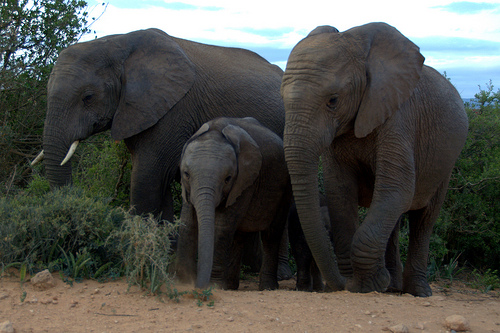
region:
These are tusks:
[24, 136, 137, 209]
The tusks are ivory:
[23, 125, 95, 177]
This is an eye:
[180, 171, 201, 182]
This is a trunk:
[200, 198, 213, 295]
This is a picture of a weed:
[98, 202, 175, 299]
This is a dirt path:
[103, 297, 213, 319]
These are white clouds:
[455, 44, 490, 86]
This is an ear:
[338, 87, 430, 124]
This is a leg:
[360, 208, 402, 263]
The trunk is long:
[261, 163, 337, 243]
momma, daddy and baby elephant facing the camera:
[18, 11, 473, 291]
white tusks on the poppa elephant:
[32, 139, 91, 164]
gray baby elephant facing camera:
[180, 111, 282, 288]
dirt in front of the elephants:
[38, 280, 465, 316]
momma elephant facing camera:
[271, 24, 487, 289]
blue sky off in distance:
[187, 9, 292, 39]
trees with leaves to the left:
[12, 10, 56, 61]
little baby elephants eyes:
[179, 163, 245, 184]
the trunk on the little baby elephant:
[199, 179, 225, 295]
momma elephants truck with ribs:
[282, 100, 350, 293]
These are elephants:
[64, 69, 421, 252]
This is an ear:
[341, 33, 422, 108]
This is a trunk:
[293, 109, 326, 241]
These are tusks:
[20, 146, 137, 167]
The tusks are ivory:
[30, 142, 178, 187]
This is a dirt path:
[35, 263, 157, 328]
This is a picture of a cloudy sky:
[170, 12, 289, 62]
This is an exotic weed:
[87, 178, 169, 291]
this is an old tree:
[8, 52, 35, 97]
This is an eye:
[153, 142, 223, 213]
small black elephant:
[152, 105, 283, 300]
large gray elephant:
[275, 11, 459, 292]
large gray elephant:
[10, 16, 185, 240]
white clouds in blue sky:
[100, 6, 141, 34]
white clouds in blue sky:
[147, 12, 192, 30]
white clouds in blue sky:
[214, 9, 265, 50]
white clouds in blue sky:
[261, 12, 279, 54]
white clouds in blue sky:
[420, 15, 447, 57]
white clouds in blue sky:
[455, 32, 495, 79]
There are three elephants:
[33, 21, 463, 302]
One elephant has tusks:
[30, 28, 179, 210]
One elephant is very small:
[174, 120, 284, 291]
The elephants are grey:
[48, 23, 469, 290]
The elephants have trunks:
[41, 23, 493, 298]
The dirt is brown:
[0, 290, 499, 330]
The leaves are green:
[1, 3, 48, 85]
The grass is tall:
[5, 195, 141, 270]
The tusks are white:
[30, 140, 82, 166]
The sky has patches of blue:
[445, 0, 499, 84]